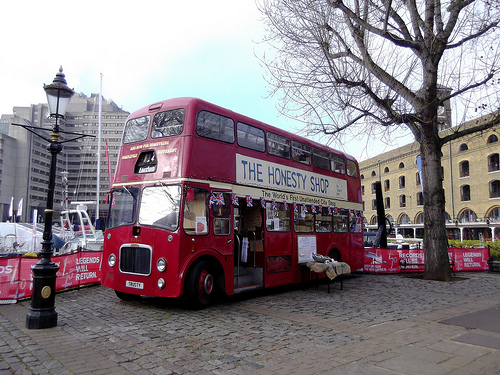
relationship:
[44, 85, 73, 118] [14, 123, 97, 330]
lamp on a post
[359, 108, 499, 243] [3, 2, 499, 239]
building in background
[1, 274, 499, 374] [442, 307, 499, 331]
ground made of blocks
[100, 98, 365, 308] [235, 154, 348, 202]
bus has a sign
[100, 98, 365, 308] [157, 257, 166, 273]
bus has a headlight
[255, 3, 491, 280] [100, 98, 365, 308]
tree beside bus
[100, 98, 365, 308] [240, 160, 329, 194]
bus has lettering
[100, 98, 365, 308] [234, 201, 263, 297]
bus has a door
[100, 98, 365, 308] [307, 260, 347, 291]
bus next to a table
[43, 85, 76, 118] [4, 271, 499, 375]
lamp on street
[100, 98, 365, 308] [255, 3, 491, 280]
bus next to a tree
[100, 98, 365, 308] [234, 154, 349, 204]
bus has a banner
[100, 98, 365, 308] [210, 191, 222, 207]
bus has a flag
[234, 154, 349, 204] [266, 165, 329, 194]
banner says hoesty shop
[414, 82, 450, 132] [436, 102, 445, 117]
tower has a clock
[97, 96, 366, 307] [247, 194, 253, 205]
double decker has flags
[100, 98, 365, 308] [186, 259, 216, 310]
bus has a wheel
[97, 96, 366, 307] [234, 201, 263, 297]
double decker has a door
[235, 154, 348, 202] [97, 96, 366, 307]
sign on a double decker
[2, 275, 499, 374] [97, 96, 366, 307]
light next to a double decker